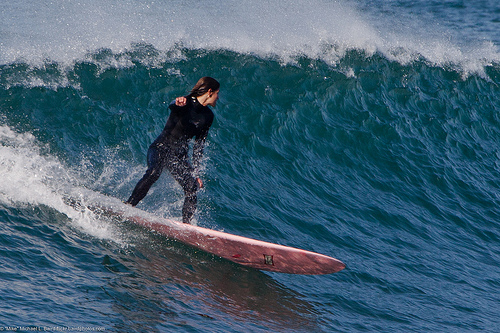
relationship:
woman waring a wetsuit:
[124, 74, 221, 224] [126, 104, 220, 216]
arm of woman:
[166, 93, 192, 113] [124, 74, 221, 224]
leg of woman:
[122, 138, 170, 212] [124, 74, 221, 224]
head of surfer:
[171, 65, 243, 121] [113, 49, 254, 193]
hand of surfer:
[165, 86, 188, 109] [124, 72, 225, 234]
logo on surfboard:
[249, 249, 276, 264] [87, 182, 384, 279]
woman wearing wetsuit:
[124, 74, 221, 224] [123, 93, 214, 225]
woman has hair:
[124, 74, 221, 224] [185, 73, 220, 93]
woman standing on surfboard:
[124, 74, 221, 224] [63, 186, 348, 276]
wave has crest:
[4, 30, 484, 174] [0, 0, 497, 68]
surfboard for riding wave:
[63, 186, 348, 276] [0, 0, 500, 100]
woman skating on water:
[124, 74, 221, 224] [1, 0, 498, 331]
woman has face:
[124, 74, 221, 224] [208, 89, 221, 112]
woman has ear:
[124, 74, 221, 224] [205, 87, 212, 97]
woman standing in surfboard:
[124, 74, 221, 224] [63, 186, 348, 276]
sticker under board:
[256, 252, 276, 269] [79, 184, 347, 283]